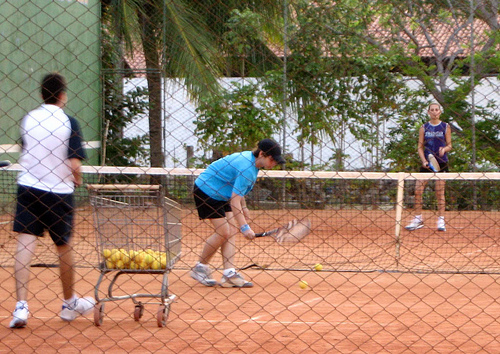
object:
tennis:
[0, 150, 499, 354]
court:
[10, 207, 484, 341]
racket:
[248, 210, 311, 247]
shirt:
[194, 145, 255, 223]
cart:
[82, 181, 181, 331]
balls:
[109, 250, 124, 262]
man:
[11, 71, 83, 329]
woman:
[408, 102, 453, 233]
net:
[0, 160, 497, 272]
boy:
[187, 135, 285, 289]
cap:
[257, 137, 285, 164]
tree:
[99, 2, 292, 204]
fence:
[315, 9, 495, 82]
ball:
[299, 281, 309, 289]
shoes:
[6, 299, 31, 331]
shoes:
[404, 219, 425, 231]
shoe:
[436, 216, 447, 232]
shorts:
[193, 182, 235, 220]